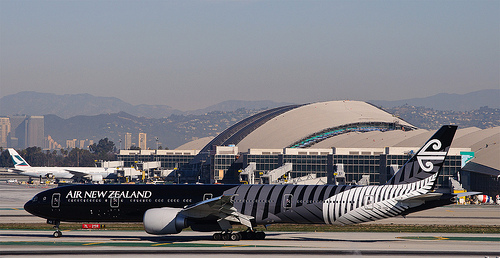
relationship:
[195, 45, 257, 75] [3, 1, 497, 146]
cloud in sky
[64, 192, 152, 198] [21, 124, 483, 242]
letters on airplane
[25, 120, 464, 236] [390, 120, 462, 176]
airplane has tail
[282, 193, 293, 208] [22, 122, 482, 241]
windows built into airplane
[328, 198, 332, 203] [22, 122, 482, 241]
window built into airplane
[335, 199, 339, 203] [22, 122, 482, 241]
window built into airplane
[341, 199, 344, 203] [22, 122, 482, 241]
window built into airplane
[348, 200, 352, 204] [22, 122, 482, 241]
window built into airplane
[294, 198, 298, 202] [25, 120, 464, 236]
window built into airplane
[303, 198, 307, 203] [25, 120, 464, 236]
window built into airplane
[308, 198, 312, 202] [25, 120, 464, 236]
window built into airplane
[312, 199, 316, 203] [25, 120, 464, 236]
window built into airplane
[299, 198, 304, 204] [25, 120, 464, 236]
window built into airplane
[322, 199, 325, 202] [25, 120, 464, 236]
window built into airplane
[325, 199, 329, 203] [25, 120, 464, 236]
window built into airplane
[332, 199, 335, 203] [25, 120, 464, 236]
window built into airplane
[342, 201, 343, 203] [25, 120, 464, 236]
window built into airplane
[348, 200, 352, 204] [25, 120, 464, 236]
window built into airplane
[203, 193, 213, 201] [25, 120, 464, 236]
windows are on airplane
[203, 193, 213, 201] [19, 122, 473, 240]
windows are on plane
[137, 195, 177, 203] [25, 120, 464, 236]
windows are on airplane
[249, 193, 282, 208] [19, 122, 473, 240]
windows are on plane